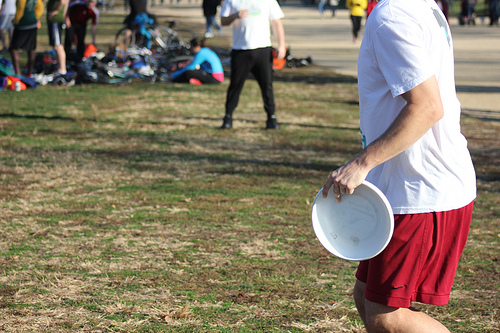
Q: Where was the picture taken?
A: In a park.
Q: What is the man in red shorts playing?
A: Frisbee.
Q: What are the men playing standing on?
A: Grass.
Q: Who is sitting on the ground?
A: A woman.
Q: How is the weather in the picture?
A: Sunny.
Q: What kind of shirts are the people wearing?
A: T-shirts.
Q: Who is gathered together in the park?
A: Small crowd.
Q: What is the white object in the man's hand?
A: Frisbee.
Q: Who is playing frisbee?
A: Two men in white shirts.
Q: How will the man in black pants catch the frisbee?
A: With his hands.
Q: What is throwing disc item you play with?
A: Frisbee.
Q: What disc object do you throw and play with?
A: Frisbee.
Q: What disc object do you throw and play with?
A: Frisbee.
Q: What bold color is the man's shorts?
A: Red.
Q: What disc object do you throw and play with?
A: Frisbee.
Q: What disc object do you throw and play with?
A: Frisbee.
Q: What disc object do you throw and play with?
A: Frisbee.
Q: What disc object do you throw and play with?
A: Frisbee.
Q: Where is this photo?
A: Outside, at a park.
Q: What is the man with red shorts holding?
A: A frisbee.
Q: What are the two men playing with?
A: A frisbee.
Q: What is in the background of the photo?
A: Many people standing and sitting.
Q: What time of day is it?
A: Early morning or afternoon.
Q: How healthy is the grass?
A: Discolored and dying.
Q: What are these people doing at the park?
A: Playing frisbee.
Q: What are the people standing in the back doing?
A: Talking together in a circle.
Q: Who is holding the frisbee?
A: Man.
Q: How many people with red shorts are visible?
A: 1.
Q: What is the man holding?
A: Frisbee.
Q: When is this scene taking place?
A: Daytime.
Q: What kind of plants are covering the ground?
A: Grass.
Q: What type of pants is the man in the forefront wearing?
A: Shorts.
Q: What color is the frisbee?
A: White.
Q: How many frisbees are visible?
A: 1.